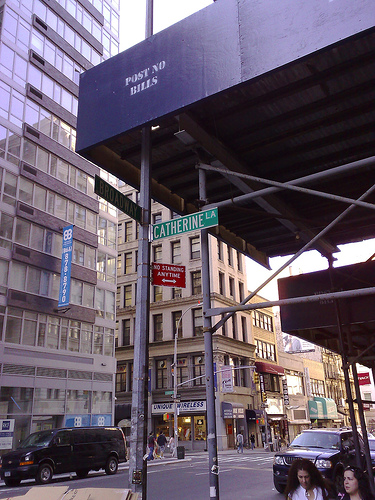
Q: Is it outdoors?
A: Yes, it is outdoors.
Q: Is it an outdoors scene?
A: Yes, it is outdoors.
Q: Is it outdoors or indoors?
A: It is outdoors.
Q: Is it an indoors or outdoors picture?
A: It is outdoors.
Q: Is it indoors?
A: No, it is outdoors.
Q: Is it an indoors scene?
A: No, it is outdoors.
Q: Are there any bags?
A: No, there are no bags.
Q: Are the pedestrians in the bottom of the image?
A: Yes, the pedestrians are in the bottom of the image.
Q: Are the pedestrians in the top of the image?
A: No, the pedestrians are in the bottom of the image.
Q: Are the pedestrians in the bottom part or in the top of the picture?
A: The pedestrians are in the bottom of the image.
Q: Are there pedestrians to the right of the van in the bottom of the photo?
A: Yes, there are pedestrians to the right of the van.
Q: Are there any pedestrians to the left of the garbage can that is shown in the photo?
A: Yes, there are pedestrians to the left of the garbage can.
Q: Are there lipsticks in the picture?
A: No, there are no lipsticks.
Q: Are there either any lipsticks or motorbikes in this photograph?
A: No, there are no lipsticks or motorbikes.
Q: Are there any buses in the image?
A: No, there are no buses.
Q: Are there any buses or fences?
A: No, there are no buses or fences.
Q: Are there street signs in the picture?
A: Yes, there is a street sign.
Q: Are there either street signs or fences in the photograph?
A: Yes, there is a street sign.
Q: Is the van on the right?
A: No, the van is on the left of the image.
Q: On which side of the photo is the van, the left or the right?
A: The van is on the left of the image.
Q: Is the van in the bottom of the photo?
A: Yes, the van is in the bottom of the image.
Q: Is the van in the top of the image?
A: No, the van is in the bottom of the image.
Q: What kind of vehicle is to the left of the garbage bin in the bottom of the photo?
A: The vehicle is a van.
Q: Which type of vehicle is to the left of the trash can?
A: The vehicle is a van.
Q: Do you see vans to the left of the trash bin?
A: Yes, there is a van to the left of the trash bin.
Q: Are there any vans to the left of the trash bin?
A: Yes, there is a van to the left of the trash bin.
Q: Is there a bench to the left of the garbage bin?
A: No, there is a van to the left of the garbage bin.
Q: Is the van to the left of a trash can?
A: Yes, the van is to the left of a trash can.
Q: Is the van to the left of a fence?
A: No, the van is to the left of a trash can.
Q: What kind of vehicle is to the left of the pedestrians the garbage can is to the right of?
A: The vehicle is a van.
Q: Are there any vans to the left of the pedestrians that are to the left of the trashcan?
A: Yes, there is a van to the left of the pedestrians.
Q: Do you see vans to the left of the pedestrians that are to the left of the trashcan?
A: Yes, there is a van to the left of the pedestrians.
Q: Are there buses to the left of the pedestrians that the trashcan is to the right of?
A: No, there is a van to the left of the pedestrians.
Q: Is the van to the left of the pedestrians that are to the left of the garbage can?
A: Yes, the van is to the left of the pedestrians.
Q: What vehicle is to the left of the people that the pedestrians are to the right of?
A: The vehicle is a van.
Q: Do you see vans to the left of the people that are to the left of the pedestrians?
A: Yes, there is a van to the left of the people.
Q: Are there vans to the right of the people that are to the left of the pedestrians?
A: No, the van is to the left of the people.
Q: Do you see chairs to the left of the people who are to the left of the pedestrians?
A: No, there is a van to the left of the people.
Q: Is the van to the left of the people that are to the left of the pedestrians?
A: Yes, the van is to the left of the people.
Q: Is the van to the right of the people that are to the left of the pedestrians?
A: No, the van is to the left of the people.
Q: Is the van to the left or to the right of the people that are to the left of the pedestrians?
A: The van is to the left of the people.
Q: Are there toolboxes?
A: No, there are no toolboxes.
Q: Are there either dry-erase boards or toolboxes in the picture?
A: No, there are no toolboxes or dry-erase boards.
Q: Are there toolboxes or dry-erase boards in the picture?
A: No, there are no toolboxes or dry-erase boards.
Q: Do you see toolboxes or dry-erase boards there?
A: No, there are no toolboxes or dry-erase boards.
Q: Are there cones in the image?
A: No, there are no cones.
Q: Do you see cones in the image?
A: No, there are no cones.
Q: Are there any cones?
A: No, there are no cones.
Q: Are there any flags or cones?
A: No, there are no cones or flags.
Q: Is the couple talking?
A: Yes, the couple is talking.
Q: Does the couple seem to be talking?
A: Yes, the couple is talking.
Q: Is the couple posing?
A: No, the couple is talking.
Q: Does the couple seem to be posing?
A: No, the couple is talking.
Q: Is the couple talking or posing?
A: The couple is talking.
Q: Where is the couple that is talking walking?
A: The couple is walking on the side walk.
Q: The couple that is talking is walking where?
A: The couple is walking on the side walk.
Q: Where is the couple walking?
A: The couple is walking on the side walk.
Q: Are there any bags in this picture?
A: No, there are no bags.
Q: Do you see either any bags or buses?
A: No, there are no bags or buses.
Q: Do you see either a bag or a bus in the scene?
A: No, there are no bags or buses.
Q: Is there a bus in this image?
A: No, there are no buses.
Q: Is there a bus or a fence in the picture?
A: No, there are no buses or fences.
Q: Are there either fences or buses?
A: No, there are no buses or fences.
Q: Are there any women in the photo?
A: Yes, there is a woman.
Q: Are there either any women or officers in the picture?
A: Yes, there is a woman.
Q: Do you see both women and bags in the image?
A: No, there is a woman but no bags.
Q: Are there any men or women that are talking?
A: Yes, the woman is talking.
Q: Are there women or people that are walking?
A: Yes, the woman is walking.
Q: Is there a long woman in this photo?
A: Yes, there is a long woman.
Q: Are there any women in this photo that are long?
A: Yes, there is a woman that is long.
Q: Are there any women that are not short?
A: Yes, there is a long woman.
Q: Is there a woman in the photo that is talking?
A: Yes, there is a woman that is talking.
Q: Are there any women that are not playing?
A: Yes, there is a woman that is talking.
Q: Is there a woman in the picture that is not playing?
A: Yes, there is a woman that is talking.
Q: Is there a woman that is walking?
A: Yes, there is a woman that is walking.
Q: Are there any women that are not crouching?
A: Yes, there is a woman that is walking.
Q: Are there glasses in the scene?
A: No, there are no glasses.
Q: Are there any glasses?
A: No, there are no glasses.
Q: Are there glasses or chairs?
A: No, there are no glasses or chairs.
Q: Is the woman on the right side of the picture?
A: Yes, the woman is on the right of the image.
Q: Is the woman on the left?
A: No, the woman is on the right of the image.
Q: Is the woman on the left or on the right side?
A: The woman is on the right of the image.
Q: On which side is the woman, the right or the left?
A: The woman is on the right of the image.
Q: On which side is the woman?
A: The woman is on the right of the image.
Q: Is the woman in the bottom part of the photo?
A: Yes, the woman is in the bottom of the image.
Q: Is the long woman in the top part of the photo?
A: No, the woman is in the bottom of the image.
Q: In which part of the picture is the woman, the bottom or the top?
A: The woman is in the bottom of the image.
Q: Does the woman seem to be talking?
A: Yes, the woman is talking.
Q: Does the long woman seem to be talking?
A: Yes, the woman is talking.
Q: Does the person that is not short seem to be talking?
A: Yes, the woman is talking.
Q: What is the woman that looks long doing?
A: The woman is talking.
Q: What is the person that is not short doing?
A: The woman is talking.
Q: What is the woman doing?
A: The woman is talking.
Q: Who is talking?
A: The woman is talking.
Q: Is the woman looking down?
A: No, the woman is talking.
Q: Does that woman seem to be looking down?
A: No, the woman is talking.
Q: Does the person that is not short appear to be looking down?
A: No, the woman is talking.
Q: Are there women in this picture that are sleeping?
A: No, there is a woman but she is talking.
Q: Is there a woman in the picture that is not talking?
A: No, there is a woman but she is talking.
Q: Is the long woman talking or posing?
A: The woman is talking.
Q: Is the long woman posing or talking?
A: The woman is talking.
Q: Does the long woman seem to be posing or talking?
A: The woman is talking.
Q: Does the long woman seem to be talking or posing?
A: The woman is talking.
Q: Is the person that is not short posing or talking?
A: The woman is talking.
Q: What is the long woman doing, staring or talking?
A: The woman is talking.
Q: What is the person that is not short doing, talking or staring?
A: The woman is talking.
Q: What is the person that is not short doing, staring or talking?
A: The woman is talking.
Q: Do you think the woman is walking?
A: Yes, the woman is walking.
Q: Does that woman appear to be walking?
A: Yes, the woman is walking.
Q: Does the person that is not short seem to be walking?
A: Yes, the woman is walking.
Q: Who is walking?
A: The woman is walking.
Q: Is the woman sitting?
A: No, the woman is walking.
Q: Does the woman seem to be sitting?
A: No, the woman is walking.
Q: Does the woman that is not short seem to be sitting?
A: No, the woman is walking.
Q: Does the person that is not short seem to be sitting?
A: No, the woman is walking.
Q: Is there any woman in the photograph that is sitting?
A: No, there is a woman but she is walking.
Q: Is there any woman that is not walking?
A: No, there is a woman but she is walking.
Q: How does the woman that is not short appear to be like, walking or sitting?
A: The woman is walking.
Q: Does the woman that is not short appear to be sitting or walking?
A: The woman is walking.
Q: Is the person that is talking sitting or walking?
A: The woman is walking.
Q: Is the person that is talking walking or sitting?
A: The woman is walking.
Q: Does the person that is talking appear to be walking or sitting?
A: The woman is walking.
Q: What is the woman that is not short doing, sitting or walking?
A: The woman is walking.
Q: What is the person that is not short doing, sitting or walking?
A: The woman is walking.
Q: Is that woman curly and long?
A: Yes, the woman is curly and long.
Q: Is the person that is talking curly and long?
A: Yes, the woman is curly and long.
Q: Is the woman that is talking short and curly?
A: No, the woman is curly but long.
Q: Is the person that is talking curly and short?
A: No, the woman is curly but long.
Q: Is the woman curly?
A: Yes, the woman is curly.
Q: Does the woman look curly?
A: Yes, the woman is curly.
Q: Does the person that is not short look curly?
A: Yes, the woman is curly.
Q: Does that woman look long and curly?
A: Yes, the woman is long and curly.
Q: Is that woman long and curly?
A: Yes, the woman is long and curly.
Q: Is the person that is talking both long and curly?
A: Yes, the woman is long and curly.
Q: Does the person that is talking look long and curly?
A: Yes, the woman is long and curly.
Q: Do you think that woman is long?
A: Yes, the woman is long.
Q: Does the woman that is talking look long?
A: Yes, the woman is long.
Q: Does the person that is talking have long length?
A: Yes, the woman is long.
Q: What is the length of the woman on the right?
A: The woman is long.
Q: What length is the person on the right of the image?
A: The woman is long.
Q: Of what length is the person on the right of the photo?
A: The woman is long.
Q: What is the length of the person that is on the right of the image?
A: The woman is long.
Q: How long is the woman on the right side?
A: The woman is long.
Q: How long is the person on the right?
A: The woman is long.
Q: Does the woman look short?
A: No, the woman is long.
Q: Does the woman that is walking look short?
A: No, the woman is long.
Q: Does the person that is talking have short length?
A: No, the woman is long.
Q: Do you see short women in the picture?
A: No, there is a woman but she is long.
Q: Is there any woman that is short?
A: No, there is a woman but she is long.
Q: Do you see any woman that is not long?
A: No, there is a woman but she is long.